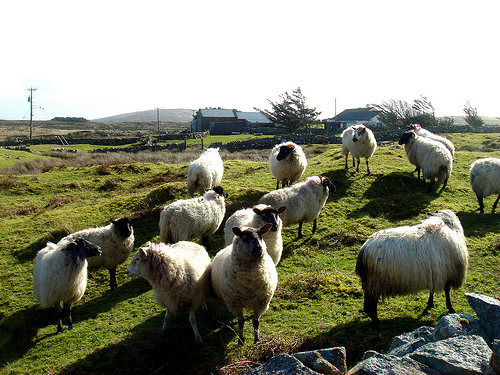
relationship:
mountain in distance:
[89, 108, 297, 124] [2, 99, 498, 167]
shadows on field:
[1, 277, 237, 375] [2, 134, 500, 373]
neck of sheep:
[147, 247, 165, 287] [127, 203, 285, 346]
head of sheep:
[257, 204, 283, 230] [127, 203, 285, 346]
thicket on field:
[31, 146, 187, 168] [2, 134, 500, 373]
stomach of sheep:
[219, 283, 260, 313] [127, 203, 285, 346]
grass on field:
[39, 330, 89, 361] [2, 134, 500, 373]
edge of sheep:
[412, 147, 453, 180] [127, 203, 285, 346]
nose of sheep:
[273, 222, 279, 231] [127, 203, 285, 346]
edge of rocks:
[332, 344, 346, 357] [293, 345, 348, 372]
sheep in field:
[34, 124, 499, 345] [5, 139, 500, 373]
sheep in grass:
[34, 124, 499, 345] [39, 330, 89, 361]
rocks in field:
[293, 345, 348, 372] [5, 139, 500, 373]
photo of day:
[5, 139, 500, 373] [12, 26, 469, 119]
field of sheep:
[5, 139, 500, 373] [127, 203, 285, 346]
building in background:
[193, 107, 273, 132] [10, 96, 500, 131]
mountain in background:
[89, 108, 297, 124] [10, 96, 500, 131]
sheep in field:
[127, 203, 285, 346] [5, 139, 500, 373]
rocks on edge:
[247, 291, 500, 374] [332, 344, 346, 357]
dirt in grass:
[3, 124, 27, 136] [4, 122, 83, 165]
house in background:
[324, 109, 388, 131] [10, 96, 500, 131]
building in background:
[193, 107, 241, 135] [10, 96, 500, 131]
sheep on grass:
[127, 203, 285, 346] [39, 330, 89, 361]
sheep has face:
[127, 203, 285, 346] [241, 230, 266, 257]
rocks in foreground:
[247, 291, 500, 374] [2, 239, 500, 374]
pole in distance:
[27, 86, 39, 140] [2, 99, 498, 167]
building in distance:
[193, 107, 241, 135] [2, 99, 498, 167]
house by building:
[324, 109, 388, 131] [193, 107, 241, 135]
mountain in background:
[84, 105, 200, 126] [10, 96, 500, 131]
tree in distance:
[252, 86, 324, 133] [2, 99, 498, 167]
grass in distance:
[39, 330, 89, 361] [2, 99, 498, 167]